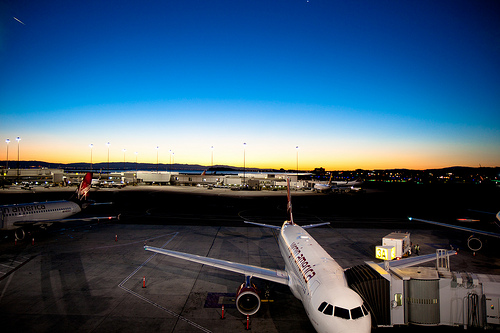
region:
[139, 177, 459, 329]
a plane at the terminal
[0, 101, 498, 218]
sunset at the airport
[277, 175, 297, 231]
the tail of a passenger jet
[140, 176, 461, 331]
a white passenger jet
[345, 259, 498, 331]
the jet way for passengers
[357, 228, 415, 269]
the baggage cart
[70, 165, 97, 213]
the red tail of a plane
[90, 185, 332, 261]
a dark taxiway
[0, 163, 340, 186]
an adjacent terminal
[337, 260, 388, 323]
the hood of a jet way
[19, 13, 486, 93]
Blue Sky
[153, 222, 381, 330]
White Airplane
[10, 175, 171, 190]
Airport terminal and lights in the background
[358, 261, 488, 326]
Loading for Passengers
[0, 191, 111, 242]
Airplane on the ground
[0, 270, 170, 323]
Airway for the aircrafts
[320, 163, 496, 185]
City lights in the distance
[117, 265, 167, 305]
Caution Cone on the airway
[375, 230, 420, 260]
Luggage being loaded on the plane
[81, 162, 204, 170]
Mountains in the distance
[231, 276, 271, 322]
engine on a plane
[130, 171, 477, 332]
plane on the ground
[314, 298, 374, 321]
cockpit window on a plane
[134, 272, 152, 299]
traffic cones on the ground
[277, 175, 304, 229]
tail wing of a plane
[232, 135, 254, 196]
light poles at an airport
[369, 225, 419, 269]
vehicle on the ground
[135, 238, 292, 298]
wing of a plane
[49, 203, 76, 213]
side windows on a plane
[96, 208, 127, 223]
red light on the wing of a plane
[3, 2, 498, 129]
Sky is dark blue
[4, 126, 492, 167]
Sky is white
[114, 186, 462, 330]
Plane parking in the airport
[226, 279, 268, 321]
Engine of plane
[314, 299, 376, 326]
Windows of cockpit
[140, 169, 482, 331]
Plane is color white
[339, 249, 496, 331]
Loading cart attached to plane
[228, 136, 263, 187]
Light poles in the airport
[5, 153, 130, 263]
Plane with red stabilizer on the airport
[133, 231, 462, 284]
Wings of plane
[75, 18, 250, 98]
the sky is blue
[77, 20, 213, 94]
the sky is clear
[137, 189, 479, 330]
the plane is white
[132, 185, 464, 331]
the plane is landed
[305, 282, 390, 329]
the plane has windows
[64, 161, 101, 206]
the tail is red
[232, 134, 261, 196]
there are street lights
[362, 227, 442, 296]
the lights are on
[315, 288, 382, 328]
the windows are black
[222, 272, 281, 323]
the plane has engines